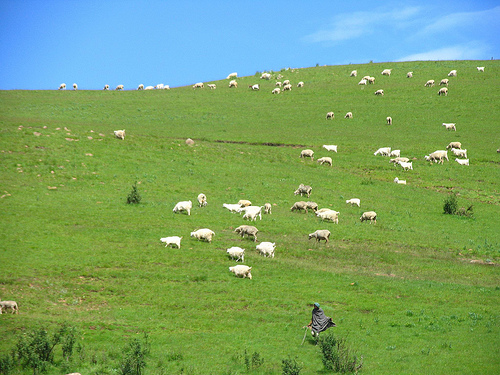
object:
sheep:
[190, 227, 215, 243]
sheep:
[159, 236, 183, 249]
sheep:
[228, 264, 253, 279]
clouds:
[316, 8, 500, 61]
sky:
[0, 0, 500, 91]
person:
[303, 301, 337, 343]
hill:
[177, 59, 500, 126]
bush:
[442, 190, 476, 220]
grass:
[265, 213, 302, 232]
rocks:
[43, 125, 48, 129]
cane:
[300, 327, 309, 345]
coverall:
[306, 308, 336, 337]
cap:
[313, 302, 321, 309]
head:
[314, 302, 321, 309]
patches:
[19, 122, 80, 145]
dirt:
[33, 131, 42, 136]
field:
[0, 90, 499, 304]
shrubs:
[114, 330, 150, 375]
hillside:
[407, 46, 453, 70]